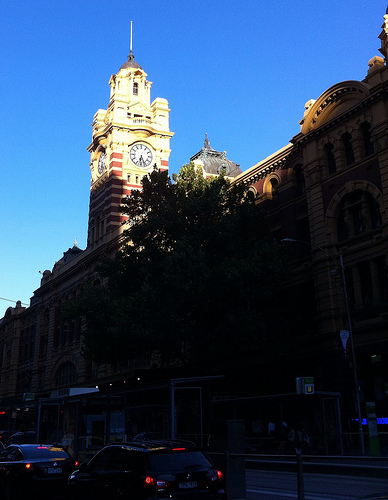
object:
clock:
[96, 150, 108, 175]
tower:
[85, 14, 175, 250]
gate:
[228, 451, 300, 499]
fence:
[216, 439, 388, 466]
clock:
[129, 143, 154, 170]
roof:
[105, 434, 198, 455]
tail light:
[143, 475, 156, 486]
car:
[104, 170, 146, 224]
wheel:
[68, 486, 85, 499]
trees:
[56, 162, 296, 454]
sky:
[0, 0, 388, 318]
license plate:
[178, 480, 198, 488]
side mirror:
[74, 460, 79, 467]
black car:
[0, 441, 79, 495]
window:
[86, 448, 138, 473]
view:
[0, 0, 388, 314]